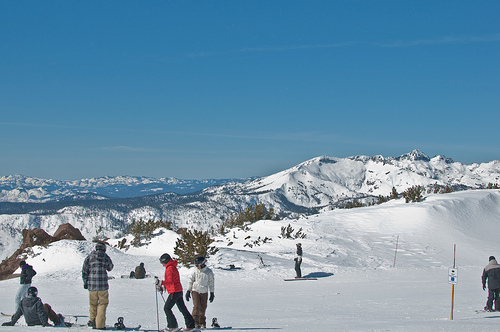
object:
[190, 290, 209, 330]
pants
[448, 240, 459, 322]
markers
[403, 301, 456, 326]
snow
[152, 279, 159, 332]
poles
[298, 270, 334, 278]
shadow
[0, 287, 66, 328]
person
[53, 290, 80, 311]
snow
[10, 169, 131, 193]
distance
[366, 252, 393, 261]
tracks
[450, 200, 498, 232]
snow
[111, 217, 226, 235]
trees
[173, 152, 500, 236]
mountain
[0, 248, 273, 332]
slope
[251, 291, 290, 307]
snow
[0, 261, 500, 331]
ground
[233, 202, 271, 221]
shrubs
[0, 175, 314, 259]
mountain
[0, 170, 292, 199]
mountains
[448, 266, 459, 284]
sign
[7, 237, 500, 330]
people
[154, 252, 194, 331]
woman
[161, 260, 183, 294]
coat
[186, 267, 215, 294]
coat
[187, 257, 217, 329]
person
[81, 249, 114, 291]
jacket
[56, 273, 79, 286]
snow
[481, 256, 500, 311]
man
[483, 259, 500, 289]
coat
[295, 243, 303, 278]
person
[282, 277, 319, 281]
skis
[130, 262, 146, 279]
person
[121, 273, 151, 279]
snowboard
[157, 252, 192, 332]
skier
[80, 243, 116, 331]
man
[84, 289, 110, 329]
pants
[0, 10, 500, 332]
scene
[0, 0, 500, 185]
sky